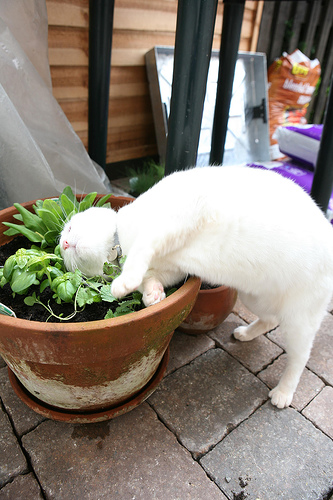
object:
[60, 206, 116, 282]
head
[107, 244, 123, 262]
tag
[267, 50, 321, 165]
bag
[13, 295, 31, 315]
soil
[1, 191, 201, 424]
pot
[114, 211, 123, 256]
collar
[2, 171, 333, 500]
sidewalk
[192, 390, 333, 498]
bricks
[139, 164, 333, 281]
fur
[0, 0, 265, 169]
sheeting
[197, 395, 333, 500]
tile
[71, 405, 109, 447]
water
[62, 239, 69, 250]
nose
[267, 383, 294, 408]
foot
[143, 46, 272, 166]
tray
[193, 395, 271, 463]
space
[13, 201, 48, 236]
leaf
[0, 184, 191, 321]
cotta planter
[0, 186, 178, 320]
green plant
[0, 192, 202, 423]
brown planter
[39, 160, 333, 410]
cat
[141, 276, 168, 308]
forepaw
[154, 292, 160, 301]
toes